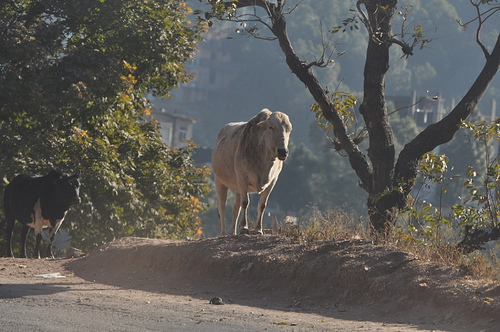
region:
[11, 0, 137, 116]
this is a tree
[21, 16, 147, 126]
the tree is tall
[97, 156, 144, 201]
the leaves are green in color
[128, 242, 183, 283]
this is the ground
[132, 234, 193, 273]
the ground is sandy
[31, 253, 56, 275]
the sand is brown in color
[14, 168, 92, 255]
this is a cow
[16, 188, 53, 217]
the fur is black and white in color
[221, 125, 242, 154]
the fur is white in color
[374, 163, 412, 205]
this is a trunk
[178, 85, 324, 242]
this is a cow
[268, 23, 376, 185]
this is a tree trunk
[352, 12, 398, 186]
this is a tree trunk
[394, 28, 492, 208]
this is a tree trunk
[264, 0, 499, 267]
this is a tree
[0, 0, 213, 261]
his is a tree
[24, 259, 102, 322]
this is some dirt on the ground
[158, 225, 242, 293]
this is some dirt on the ground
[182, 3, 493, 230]
trees and houses on hill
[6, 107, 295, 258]
two standing cows facing camera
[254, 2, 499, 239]
tree with three branches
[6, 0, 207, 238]
green leaves on tree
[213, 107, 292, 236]
front and side of cow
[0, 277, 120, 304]
shadow of cow on dirt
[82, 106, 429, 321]
cow on dirt hill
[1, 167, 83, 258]
cow with black and white coat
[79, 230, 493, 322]
light and shadows on dirt hill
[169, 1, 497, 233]
haze over mountain side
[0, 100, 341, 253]
two cows are walking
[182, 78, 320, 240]
the cow is white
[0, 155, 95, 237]
the cow is black with some white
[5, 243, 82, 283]
the road is made of dirt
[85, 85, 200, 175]
house in the background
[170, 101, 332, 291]
cow on a small dirt hill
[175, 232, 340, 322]
dirt hill next to the road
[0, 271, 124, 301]
shadow of the cow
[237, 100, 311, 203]
sun is on the cow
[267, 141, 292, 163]
the nose is black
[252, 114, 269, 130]
Right ear on cow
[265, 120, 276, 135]
Right eye on cow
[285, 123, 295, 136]
Left eye of cow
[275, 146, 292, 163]
Nose of the cow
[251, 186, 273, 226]
Front left leg of cow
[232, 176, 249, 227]
Front right leg of cow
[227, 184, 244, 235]
Back left leg of cow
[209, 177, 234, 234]
Back right leg of cow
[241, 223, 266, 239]
Front hooves of cow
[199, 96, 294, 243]
White cow next to tree